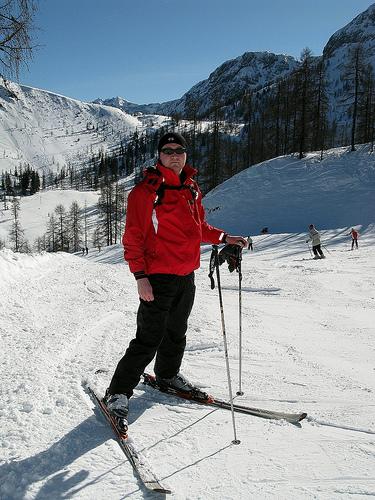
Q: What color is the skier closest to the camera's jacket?
A: Red.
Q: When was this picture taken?
A: Daytime.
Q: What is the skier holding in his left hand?
A: A ski pole.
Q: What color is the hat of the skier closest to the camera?
A: Black.